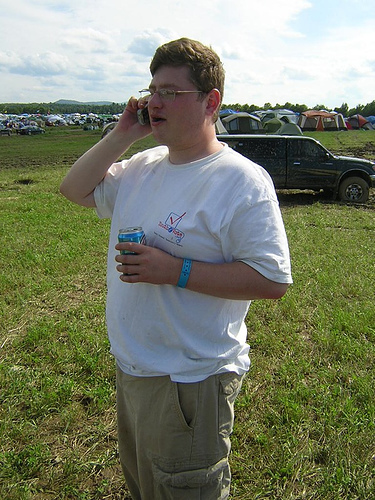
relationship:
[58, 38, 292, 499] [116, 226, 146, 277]
man has can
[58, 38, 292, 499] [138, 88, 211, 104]
man has glasses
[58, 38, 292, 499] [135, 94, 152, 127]
man has cellphone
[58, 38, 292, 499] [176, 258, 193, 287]
man has wrist band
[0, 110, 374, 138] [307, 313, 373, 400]
tents on grass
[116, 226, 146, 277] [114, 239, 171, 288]
can on hand